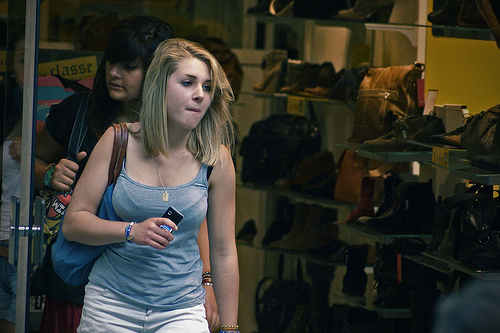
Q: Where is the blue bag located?
A: On her shoulder.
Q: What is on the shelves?
A: Handbags.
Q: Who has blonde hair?
A: The girl.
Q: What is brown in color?
A: A bag.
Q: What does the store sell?
A: Bags.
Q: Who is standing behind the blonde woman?
A: A woman with black hair.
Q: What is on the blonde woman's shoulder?
A: A blue purse.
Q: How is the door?
A: Open.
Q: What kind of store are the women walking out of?
A: Purse store.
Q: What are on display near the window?
A: Purses.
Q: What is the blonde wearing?
A: Blue tank top.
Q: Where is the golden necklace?
A: Around the blonde's neck.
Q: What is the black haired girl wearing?
A: Black clothes.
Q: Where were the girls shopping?
A: Purse store.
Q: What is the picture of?
A: Two women in a shop.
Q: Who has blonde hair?
A: The woman in front.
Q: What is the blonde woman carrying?
A: A blue purse on right shoulder.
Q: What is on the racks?
A: New purses for sale.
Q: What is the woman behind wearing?
A: A black shirt.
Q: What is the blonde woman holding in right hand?
A: A cell phone.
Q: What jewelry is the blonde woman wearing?
A: A gold necklace and a bracelet.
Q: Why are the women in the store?
A: Shopping.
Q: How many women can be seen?
A: Two.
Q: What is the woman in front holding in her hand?
A: Phone.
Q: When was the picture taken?
A: Daytime.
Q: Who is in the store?
A: Women.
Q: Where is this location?
A: Store.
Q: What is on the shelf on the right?
A: Shoes and purses.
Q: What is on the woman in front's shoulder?
A: Bag.